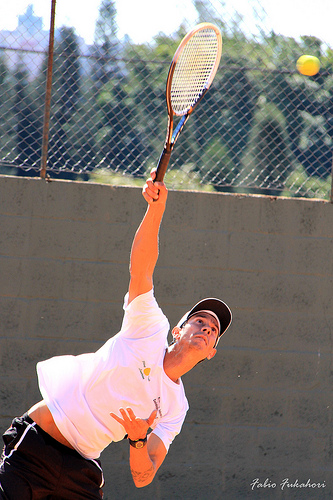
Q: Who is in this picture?
A: Tennis player.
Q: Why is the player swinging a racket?
A: To hit the ball.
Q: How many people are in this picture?
A: One.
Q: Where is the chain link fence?
A: On top of the cement wall.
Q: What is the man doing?
A: Playing tennis.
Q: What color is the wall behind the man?
A: Grey.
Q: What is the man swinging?
A: A tennis racquet.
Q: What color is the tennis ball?
A: Yellow.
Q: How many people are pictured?
A: One.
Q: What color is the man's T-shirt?
A: White.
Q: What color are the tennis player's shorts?
A: Black with a white stripe.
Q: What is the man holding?
A: A tennis racket.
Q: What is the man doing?
A: Hitting a tennis ball.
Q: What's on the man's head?
A: Hat.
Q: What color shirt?
A: White.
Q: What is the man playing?
A: Tennis.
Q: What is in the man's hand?
A: Racket.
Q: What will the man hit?
A: Ball.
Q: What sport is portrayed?
A: Tennis.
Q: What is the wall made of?
A: Concrete.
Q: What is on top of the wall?
A: Fence.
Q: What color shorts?
A: Black.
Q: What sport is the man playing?
A: Tennis.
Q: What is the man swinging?
A: A tennis racquet.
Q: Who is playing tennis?
A: A man.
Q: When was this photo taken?
A: Daytime.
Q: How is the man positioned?
A: With his right arm up.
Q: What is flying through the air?
A: A tennis ball.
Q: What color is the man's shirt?
A: White.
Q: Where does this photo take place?
A: On a tennis court.